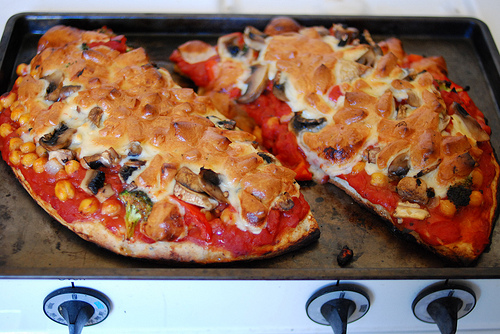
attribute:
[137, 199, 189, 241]
mushroom — juicy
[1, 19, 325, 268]
pizza — slice, delicious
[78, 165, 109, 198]
mushroom — juicy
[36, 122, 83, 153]
mushroom — juicy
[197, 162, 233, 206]
mushroom — juicy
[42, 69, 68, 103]
mushroom — juicy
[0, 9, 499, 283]
pan — metal, baking pan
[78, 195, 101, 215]
corn — yellow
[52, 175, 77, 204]
corn — yellow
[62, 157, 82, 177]
corn — yellow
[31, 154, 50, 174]
corn — yellow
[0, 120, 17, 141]
corn — yellow